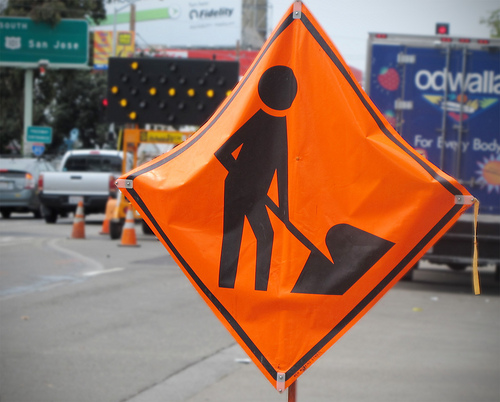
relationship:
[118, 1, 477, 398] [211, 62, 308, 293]
sign with man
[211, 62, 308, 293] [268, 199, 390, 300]
man holding shovel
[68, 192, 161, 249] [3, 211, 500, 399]
cones on road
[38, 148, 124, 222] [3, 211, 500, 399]
cars on road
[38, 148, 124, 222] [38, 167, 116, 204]
cars has back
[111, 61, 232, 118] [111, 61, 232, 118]
arrow has arrow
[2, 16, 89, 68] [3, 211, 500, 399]
sign above road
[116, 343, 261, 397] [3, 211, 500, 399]
scratch on road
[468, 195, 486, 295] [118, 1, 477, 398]
ribbon hanging off of sign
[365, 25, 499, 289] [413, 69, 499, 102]
truck says odwalla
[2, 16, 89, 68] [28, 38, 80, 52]
sign says san jose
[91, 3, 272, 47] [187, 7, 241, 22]
banner says fidelity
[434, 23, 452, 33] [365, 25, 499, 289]
light above truck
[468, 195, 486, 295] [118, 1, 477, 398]
ribbon hanging from sign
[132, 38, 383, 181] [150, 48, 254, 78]
building has roof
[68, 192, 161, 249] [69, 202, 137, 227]
cones have stripes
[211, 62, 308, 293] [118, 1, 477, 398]
man on sign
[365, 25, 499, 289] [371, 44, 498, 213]
truck has back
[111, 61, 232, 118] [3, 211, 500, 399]
arrow on road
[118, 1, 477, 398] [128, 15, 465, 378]
sign has border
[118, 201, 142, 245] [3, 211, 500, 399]
cone on road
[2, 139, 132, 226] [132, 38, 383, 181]
cars in front of building